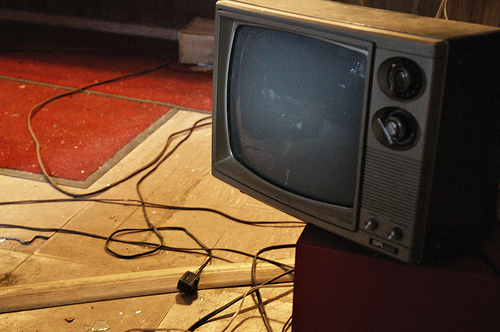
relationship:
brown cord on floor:
[0, 58, 291, 329] [4, 44, 306, 329]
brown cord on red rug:
[0, 58, 291, 329] [34, 92, 161, 174]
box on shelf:
[170, 10, 228, 70] [5, 0, 185, 50]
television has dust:
[210, 1, 497, 262] [314, 4, 456, 44]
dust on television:
[314, 4, 456, 44] [210, 1, 497, 262]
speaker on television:
[358, 143, 421, 228] [210, 1, 497, 262]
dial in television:
[364, 217, 377, 230] [210, 1, 497, 262]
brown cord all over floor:
[0, 58, 291, 329] [4, 44, 306, 329]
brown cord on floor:
[0, 58, 291, 329] [108, 142, 210, 231]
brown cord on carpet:
[25, 61, 192, 243] [3, 49, 213, 192]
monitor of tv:
[234, 46, 380, 227] [187, 7, 494, 279]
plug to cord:
[175, 268, 200, 295] [15, 40, 290, 330]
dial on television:
[364, 218, 378, 231] [208, 1, 498, 262]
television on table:
[208, 1, 498, 262] [290, 220, 495, 328]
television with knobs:
[208, 1, 498, 262] [377, 109, 412, 148]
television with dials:
[208, 1, 498, 262] [386, 227, 401, 242]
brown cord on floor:
[0, 58, 291, 329] [10, 48, 283, 329]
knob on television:
[379, 63, 414, 95] [210, 1, 497, 262]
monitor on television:
[227, 24, 372, 207] [210, 1, 497, 262]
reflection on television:
[243, 58, 327, 145] [210, 1, 497, 262]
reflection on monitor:
[243, 58, 327, 145] [227, 24, 372, 207]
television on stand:
[210, 1, 497, 262] [289, 212, 497, 327]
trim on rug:
[69, 96, 174, 196] [18, 63, 197, 220]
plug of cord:
[176, 270, 201, 293] [4, 61, 307, 330]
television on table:
[208, 1, 498, 262] [272, 215, 494, 330]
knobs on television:
[370, 49, 425, 159] [208, 1, 498, 262]